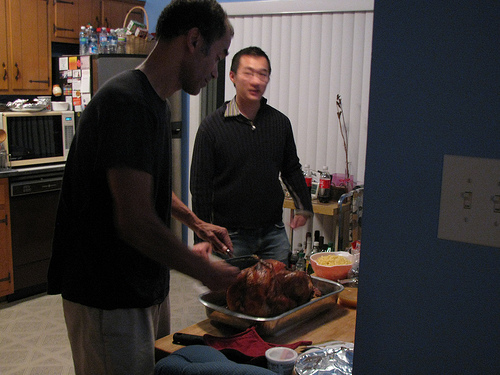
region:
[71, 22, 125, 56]
water bottles on a refrigerator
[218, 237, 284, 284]
knife cutting turkey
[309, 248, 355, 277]
bowl of mac and cheese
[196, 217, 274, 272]
hand holding a knife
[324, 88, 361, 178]
microphone stand in front of white curtain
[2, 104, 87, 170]
white trimmed microwave oven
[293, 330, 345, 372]
plate covered in aluminum foil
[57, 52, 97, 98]
notes on a refrigerator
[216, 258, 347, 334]
turkey in a silver pan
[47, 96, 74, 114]
white dish on a microwave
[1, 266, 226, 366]
Grey and beige colored floors.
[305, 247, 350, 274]
An orange and white bowl.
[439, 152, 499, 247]
A light switch panel.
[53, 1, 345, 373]
A man cutting a turkey.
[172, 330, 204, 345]
A black handle.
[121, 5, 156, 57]
A brown woven basket with a handle.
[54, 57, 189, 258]
A black and silver refrigerator.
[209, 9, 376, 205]
Long white blinds.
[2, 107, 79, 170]
A stainless steel microwave.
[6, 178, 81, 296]
A black dishwasher.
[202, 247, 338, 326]
a roasted turkey in a pan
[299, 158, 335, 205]
two coke bottles on a table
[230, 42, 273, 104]
a head of a man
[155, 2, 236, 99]
a head of a man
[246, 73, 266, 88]
the nose of a man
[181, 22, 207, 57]
the ear of a man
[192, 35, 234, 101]
the profile of a man's face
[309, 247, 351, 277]
food in a bowl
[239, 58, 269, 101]
the face of a man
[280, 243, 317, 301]
a leg of a roasted turkey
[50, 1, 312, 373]
two men in a kitchen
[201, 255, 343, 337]
a chicken on a metal tray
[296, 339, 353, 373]
crumpled aluminum paper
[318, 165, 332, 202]
a plastic bottle of soda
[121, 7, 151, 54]
a wicker basket on top of a fridge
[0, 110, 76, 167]
a white microwave in a kitchen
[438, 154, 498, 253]
white light switch on a blue wall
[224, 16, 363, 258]
white vertical blinds in a kitchen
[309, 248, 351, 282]
an range bowl on a counter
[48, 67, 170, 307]
man wearing a black shirt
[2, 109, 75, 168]
A silver and black microwave.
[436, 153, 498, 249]
A white light switch panel.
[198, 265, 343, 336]
A silver pan.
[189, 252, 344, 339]
A brown turkey in a pan.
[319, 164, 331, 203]
A clear bottle with a red label.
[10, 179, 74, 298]
A black dishwasher.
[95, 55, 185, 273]
A silver and black refrigerator.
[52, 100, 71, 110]
A white bowl.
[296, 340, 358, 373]
Silver aluminum foil.